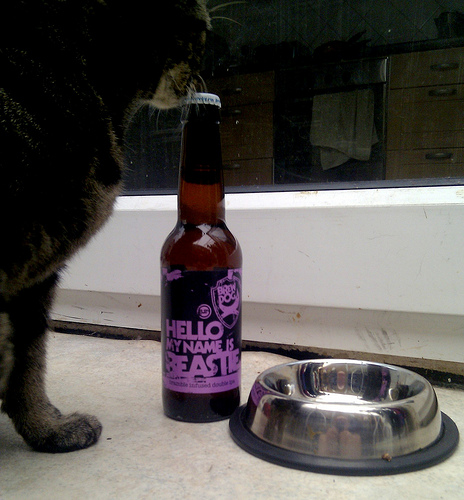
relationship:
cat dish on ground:
[229, 357, 461, 478] [99, 337, 449, 496]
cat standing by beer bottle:
[1, 4, 216, 455] [159, 93, 243, 423]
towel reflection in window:
[305, 86, 381, 171] [110, 7, 431, 359]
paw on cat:
[19, 397, 106, 454] [2, 1, 242, 456]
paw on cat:
[32, 409, 103, 453] [1, 4, 216, 455]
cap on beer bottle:
[182, 91, 223, 109] [159, 93, 243, 423]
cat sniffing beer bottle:
[1, 4, 216, 455] [159, 93, 243, 423]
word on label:
[161, 320, 224, 345] [155, 260, 246, 396]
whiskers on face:
[179, 72, 211, 125] [160, 1, 215, 117]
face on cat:
[160, 1, 215, 117] [1, 4, 216, 455]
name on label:
[181, 339, 225, 358] [155, 260, 246, 396]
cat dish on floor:
[229, 357, 461, 478] [85, 369, 211, 494]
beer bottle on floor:
[159, 93, 243, 423] [85, 369, 211, 494]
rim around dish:
[256, 458, 441, 476] [246, 354, 446, 467]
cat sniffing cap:
[1, 4, 216, 455] [179, 87, 228, 104]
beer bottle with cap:
[159, 93, 243, 423] [180, 89, 227, 108]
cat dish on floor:
[215, 347, 458, 498] [86, 415, 223, 493]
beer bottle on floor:
[155, 75, 250, 450] [85, 369, 211, 494]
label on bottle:
[158, 270, 243, 390] [144, 78, 251, 431]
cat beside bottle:
[1, 4, 216, 455] [141, 80, 277, 446]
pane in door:
[101, 10, 457, 189] [142, 10, 459, 360]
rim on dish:
[256, 435, 393, 498] [222, 341, 458, 497]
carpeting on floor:
[16, 330, 258, 492] [85, 369, 211, 494]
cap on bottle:
[160, 64, 235, 127] [141, 65, 256, 448]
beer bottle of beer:
[159, 93, 243, 423] [160, 92, 243, 422]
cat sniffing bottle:
[1, 4, 216, 455] [107, 53, 265, 488]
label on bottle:
[139, 283, 247, 385] [137, 264, 261, 406]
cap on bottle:
[182, 91, 223, 109] [149, 52, 288, 475]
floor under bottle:
[85, 369, 211, 494] [130, 59, 272, 459]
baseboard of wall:
[86, 184, 461, 313] [103, 183, 462, 399]